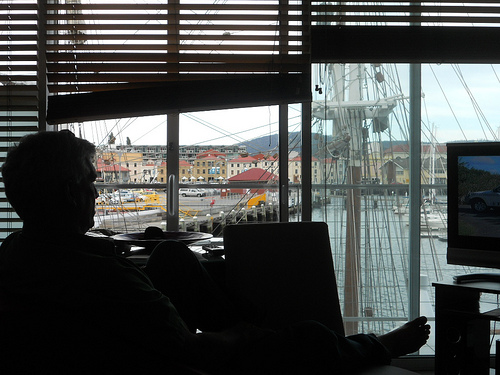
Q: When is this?
A: Daytime.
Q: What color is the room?
A: Dark.